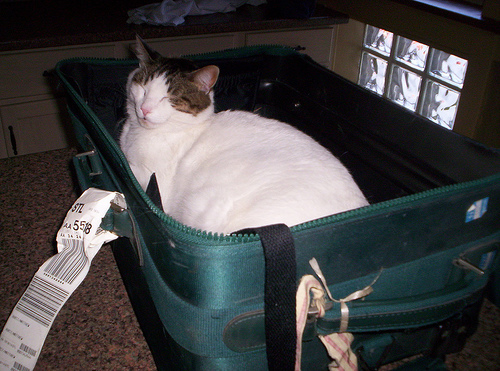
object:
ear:
[133, 33, 165, 68]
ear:
[188, 64, 222, 95]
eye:
[135, 82, 148, 95]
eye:
[157, 95, 173, 104]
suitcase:
[38, 42, 499, 371]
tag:
[0, 186, 129, 371]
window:
[364, 23, 395, 60]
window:
[393, 35, 431, 74]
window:
[425, 47, 469, 91]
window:
[358, 50, 390, 97]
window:
[385, 63, 424, 116]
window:
[417, 78, 463, 132]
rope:
[228, 223, 299, 371]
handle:
[313, 267, 492, 336]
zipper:
[53, 43, 500, 244]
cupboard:
[0, 98, 71, 160]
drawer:
[245, 28, 334, 63]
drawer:
[129, 35, 235, 62]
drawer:
[0, 45, 117, 99]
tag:
[464, 196, 491, 225]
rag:
[123, 1, 267, 26]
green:
[176, 240, 499, 371]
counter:
[0, 0, 350, 50]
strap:
[295, 257, 378, 371]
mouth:
[137, 114, 157, 126]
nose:
[139, 105, 154, 116]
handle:
[7, 125, 18, 156]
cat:
[115, 31, 372, 236]